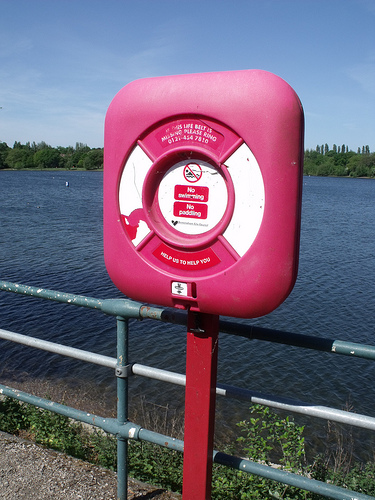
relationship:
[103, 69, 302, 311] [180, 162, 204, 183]
sign says no swimming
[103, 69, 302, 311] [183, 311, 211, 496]
sign has a stand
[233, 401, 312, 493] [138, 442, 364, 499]
weeds are beside bank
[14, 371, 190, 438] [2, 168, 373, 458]
grass beside lake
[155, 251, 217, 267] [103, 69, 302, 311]
writing on sign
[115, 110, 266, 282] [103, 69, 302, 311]
diagram on sign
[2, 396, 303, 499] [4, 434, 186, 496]
ground has gravel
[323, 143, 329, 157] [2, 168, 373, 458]
tree next to water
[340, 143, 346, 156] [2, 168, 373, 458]
tree next to water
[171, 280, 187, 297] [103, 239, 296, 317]
logo on bottom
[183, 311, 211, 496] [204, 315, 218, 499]
pole has an edge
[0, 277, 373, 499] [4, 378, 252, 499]
bridge has an edge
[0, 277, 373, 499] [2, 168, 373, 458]
fence beside water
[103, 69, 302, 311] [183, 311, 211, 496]
sign on top of pole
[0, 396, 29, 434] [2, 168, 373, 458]
plant beside water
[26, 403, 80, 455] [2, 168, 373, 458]
plant beside water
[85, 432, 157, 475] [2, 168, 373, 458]
plant beside water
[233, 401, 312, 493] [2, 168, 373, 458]
plant beside water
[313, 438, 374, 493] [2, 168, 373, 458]
plant beside water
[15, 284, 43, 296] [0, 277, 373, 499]
paint on fence